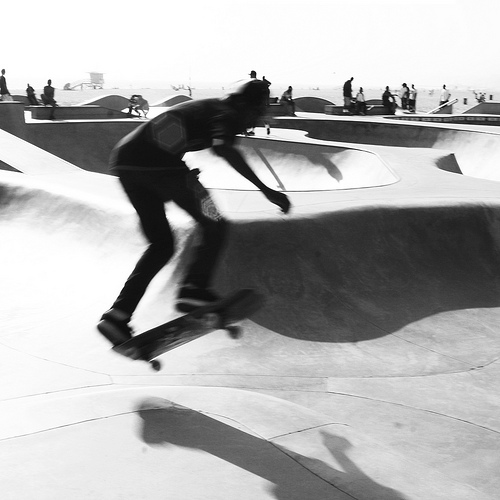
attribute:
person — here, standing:
[336, 68, 381, 124]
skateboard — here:
[107, 267, 265, 384]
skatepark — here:
[20, 13, 437, 470]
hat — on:
[243, 70, 287, 140]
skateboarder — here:
[121, 8, 297, 336]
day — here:
[53, 35, 404, 299]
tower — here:
[90, 41, 127, 114]